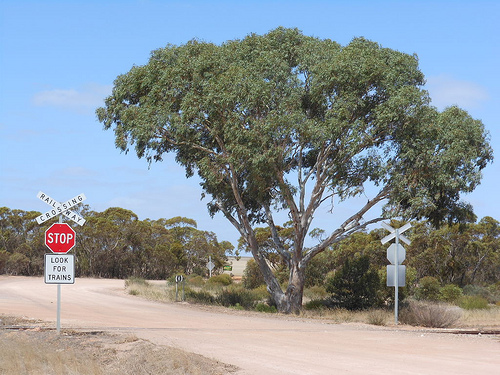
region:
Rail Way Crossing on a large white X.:
[36, 191, 86, 226]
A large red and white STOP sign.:
[41, 223, 76, 253]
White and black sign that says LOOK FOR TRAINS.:
[42, 250, 77, 286]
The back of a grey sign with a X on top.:
[380, 220, 411, 322]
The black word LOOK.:
[47, 253, 71, 265]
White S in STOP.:
[46, 230, 53, 244]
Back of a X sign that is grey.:
[379, 215, 413, 245]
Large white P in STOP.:
[66, 230, 73, 245]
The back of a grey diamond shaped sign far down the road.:
[203, 260, 215, 271]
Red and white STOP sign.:
[46, 221, 76, 254]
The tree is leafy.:
[100, 38, 492, 230]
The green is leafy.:
[93, 40, 477, 242]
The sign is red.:
[40, 219, 77, 252]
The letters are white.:
[37, 224, 78, 245]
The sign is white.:
[45, 252, 74, 287]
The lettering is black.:
[40, 255, 72, 287]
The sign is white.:
[25, 184, 89, 229]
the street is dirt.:
[7, 266, 490, 373]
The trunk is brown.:
[235, 213, 317, 315]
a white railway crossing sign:
[26, 182, 103, 231]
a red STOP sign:
[32, 221, 90, 273]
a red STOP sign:
[33, 204, 113, 269]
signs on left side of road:
[30, 185, 111, 345]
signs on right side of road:
[373, 205, 423, 339]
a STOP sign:
[38, 221, 82, 255]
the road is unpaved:
[33, 276, 408, 373]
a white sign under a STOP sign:
[43, 223, 75, 288]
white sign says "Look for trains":
[42, 253, 79, 289]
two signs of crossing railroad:
[22, 186, 93, 225]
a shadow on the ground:
[410, 310, 495, 349]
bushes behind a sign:
[341, 203, 493, 335]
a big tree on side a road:
[117, 20, 484, 325]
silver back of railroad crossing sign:
[375, 219, 415, 319]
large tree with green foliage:
[97, 30, 494, 312]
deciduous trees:
[1, 30, 498, 312]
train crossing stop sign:
[32, 190, 83, 342]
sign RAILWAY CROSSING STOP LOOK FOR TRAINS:
[36, 192, 82, 336]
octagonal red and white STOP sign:
[42, 221, 74, 252]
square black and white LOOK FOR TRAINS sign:
[42, 252, 72, 282]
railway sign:
[173, 273, 183, 301]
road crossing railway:
[0, 273, 496, 373]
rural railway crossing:
[0, 0, 495, 372]